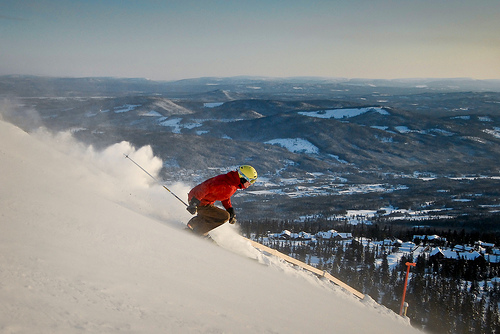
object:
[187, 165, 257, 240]
woman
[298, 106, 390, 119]
snow patch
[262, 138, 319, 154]
snow patch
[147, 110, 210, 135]
snow patch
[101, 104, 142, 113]
snow patch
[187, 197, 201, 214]
glove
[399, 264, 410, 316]
pole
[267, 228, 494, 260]
buildings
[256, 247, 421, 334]
track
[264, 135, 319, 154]
snow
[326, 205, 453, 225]
snow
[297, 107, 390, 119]
snow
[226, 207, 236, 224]
glove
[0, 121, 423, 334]
snow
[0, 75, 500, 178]
hills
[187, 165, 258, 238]
man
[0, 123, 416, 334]
slope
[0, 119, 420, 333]
hill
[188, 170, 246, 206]
coat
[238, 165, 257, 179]
helmet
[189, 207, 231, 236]
pants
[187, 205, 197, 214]
hand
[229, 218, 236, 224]
hand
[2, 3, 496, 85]
air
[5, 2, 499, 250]
background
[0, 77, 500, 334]
ground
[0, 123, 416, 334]
mountain